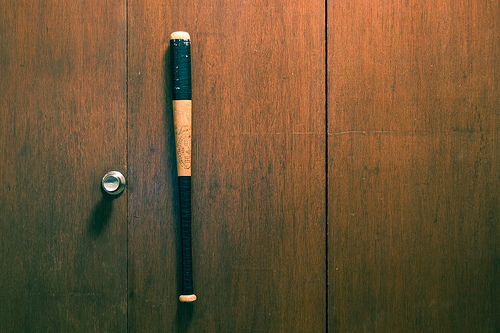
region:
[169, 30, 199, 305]
wooden baseball bat on table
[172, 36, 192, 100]
tape showing on bat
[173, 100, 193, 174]
wood showing with burns on it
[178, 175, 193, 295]
grip tape on bottom of bat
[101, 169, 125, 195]
metal object sits on table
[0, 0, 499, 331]
wooden table with bat and object on it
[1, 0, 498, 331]
table made up of three seperate pieces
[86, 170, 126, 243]
object casts shadow on table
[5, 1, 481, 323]
a baseball bat lying on a table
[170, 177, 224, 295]
black tape wrapped around a bat's grip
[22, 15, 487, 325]
a wall with wood panelling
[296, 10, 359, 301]
a seam between 2 panels of wood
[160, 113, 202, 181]
a stamp in the wood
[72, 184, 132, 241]
a shadow cast by the door knob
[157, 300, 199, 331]
a shadow cast by the bat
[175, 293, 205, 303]
the very end of a baseball bat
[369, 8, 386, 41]
brown specks in door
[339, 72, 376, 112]
brown specks in door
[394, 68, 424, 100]
brown specks in door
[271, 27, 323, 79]
brown specks in door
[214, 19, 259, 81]
brown specks in door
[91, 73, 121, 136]
brown specks in door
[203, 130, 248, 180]
brown specks in door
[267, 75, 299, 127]
black strike on door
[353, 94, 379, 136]
black strike on door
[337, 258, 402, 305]
black strike on door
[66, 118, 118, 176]
black strike on door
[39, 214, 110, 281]
black strike on door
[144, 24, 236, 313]
baseball bat on door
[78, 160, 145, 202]
silver doorknob on door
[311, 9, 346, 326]
space between door panels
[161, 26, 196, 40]
Tip of wooden bat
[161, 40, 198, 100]
black tape across bat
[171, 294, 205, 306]
End knob of bat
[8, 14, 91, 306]
Dark wood grain door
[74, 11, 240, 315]
bat and door knob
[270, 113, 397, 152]
scuff across two panels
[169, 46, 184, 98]
white specs along tape